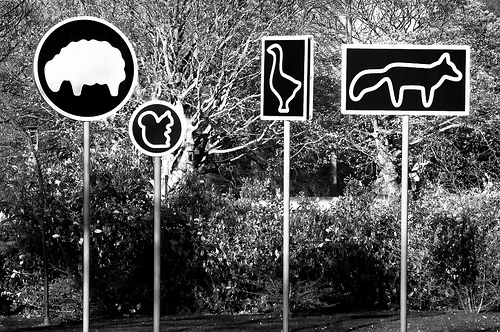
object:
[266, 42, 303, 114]
bird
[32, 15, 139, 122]
black sign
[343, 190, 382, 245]
ground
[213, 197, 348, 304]
bush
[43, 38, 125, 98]
sheep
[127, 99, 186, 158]
sign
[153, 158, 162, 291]
pole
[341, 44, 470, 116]
sign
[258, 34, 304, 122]
picture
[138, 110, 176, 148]
squirrel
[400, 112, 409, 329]
pole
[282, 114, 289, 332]
pole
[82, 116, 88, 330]
pole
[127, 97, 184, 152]
picture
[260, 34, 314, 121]
duck sign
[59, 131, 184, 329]
pole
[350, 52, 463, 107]
fox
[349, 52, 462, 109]
symbol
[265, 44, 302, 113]
symbol